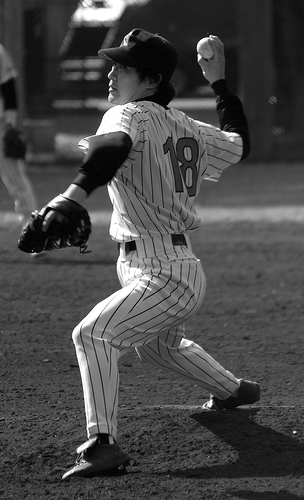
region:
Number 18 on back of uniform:
[159, 132, 201, 200]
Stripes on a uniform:
[67, 98, 243, 440]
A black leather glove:
[11, 192, 94, 258]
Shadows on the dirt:
[159, 403, 300, 497]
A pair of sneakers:
[59, 376, 265, 481]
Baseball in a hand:
[192, 30, 230, 83]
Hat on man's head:
[97, 24, 177, 107]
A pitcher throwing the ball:
[13, 25, 266, 484]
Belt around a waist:
[113, 227, 192, 257]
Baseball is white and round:
[193, 35, 222, 56]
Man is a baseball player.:
[18, 4, 262, 496]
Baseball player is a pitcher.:
[54, 22, 260, 475]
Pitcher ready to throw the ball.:
[56, 24, 258, 480]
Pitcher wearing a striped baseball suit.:
[69, 100, 242, 435]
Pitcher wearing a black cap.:
[93, 22, 182, 78]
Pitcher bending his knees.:
[60, 278, 227, 424]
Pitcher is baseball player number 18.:
[161, 130, 200, 195]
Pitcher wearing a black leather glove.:
[12, 189, 90, 252]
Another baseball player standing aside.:
[0, 33, 46, 258]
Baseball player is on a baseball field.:
[2, 132, 295, 495]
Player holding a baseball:
[197, 40, 228, 57]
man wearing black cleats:
[55, 430, 127, 479]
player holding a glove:
[14, 182, 91, 268]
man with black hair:
[140, 48, 178, 98]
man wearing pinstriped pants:
[83, 300, 122, 429]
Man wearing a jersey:
[113, 113, 198, 236]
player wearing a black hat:
[112, 27, 176, 94]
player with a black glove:
[22, 196, 77, 237]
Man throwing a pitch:
[188, 32, 230, 86]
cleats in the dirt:
[60, 401, 140, 480]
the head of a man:
[106, 19, 182, 123]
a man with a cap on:
[92, 36, 195, 125]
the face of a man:
[92, 36, 176, 120]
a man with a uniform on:
[74, 66, 261, 469]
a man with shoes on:
[59, 346, 290, 480]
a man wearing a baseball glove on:
[21, 112, 176, 261]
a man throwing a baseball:
[47, 4, 260, 313]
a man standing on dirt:
[50, 299, 294, 475]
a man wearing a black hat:
[82, 17, 217, 116]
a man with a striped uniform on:
[60, 91, 252, 460]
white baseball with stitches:
[193, 31, 223, 59]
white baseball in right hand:
[189, 24, 228, 80]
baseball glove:
[18, 192, 93, 258]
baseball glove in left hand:
[22, 190, 94, 258]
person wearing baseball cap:
[104, 31, 179, 76]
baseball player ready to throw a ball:
[55, 20, 254, 309]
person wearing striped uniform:
[99, 82, 224, 315]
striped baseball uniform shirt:
[109, 87, 216, 247]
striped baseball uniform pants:
[66, 273, 229, 441]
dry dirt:
[22, 352, 61, 405]